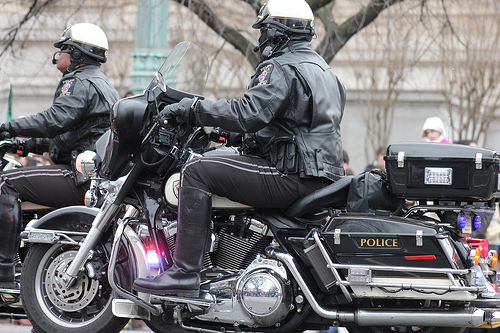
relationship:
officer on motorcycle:
[132, 0, 346, 297] [20, 42, 500, 332]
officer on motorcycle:
[0, 21, 121, 289] [0, 135, 55, 316]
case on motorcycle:
[386, 143, 500, 202] [20, 42, 500, 332]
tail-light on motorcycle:
[467, 235, 489, 259] [20, 42, 500, 332]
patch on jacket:
[249, 63, 272, 89] [192, 36, 346, 180]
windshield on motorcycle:
[157, 40, 208, 95] [20, 42, 500, 332]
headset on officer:
[251, 37, 267, 53] [132, 0, 346, 297]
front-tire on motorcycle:
[20, 243, 131, 332] [20, 42, 500, 332]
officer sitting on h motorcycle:
[132, 0, 346, 297] [20, 42, 500, 332]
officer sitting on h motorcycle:
[0, 21, 121, 289] [0, 135, 55, 316]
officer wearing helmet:
[0, 21, 121, 289] [55, 22, 108, 62]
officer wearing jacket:
[0, 21, 121, 289] [2, 63, 122, 163]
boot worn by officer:
[135, 186, 213, 298] [132, 0, 346, 297]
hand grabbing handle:
[0, 122, 11, 131] [2, 128, 11, 139]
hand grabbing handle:
[157, 100, 181, 128] [161, 115, 170, 126]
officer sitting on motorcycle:
[132, 0, 346, 297] [20, 42, 500, 332]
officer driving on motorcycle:
[132, 0, 346, 297] [20, 42, 500, 332]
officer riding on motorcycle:
[132, 0, 346, 297] [20, 42, 500, 332]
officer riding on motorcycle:
[0, 21, 121, 289] [0, 135, 55, 316]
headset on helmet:
[50, 48, 71, 64] [55, 22, 108, 62]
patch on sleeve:
[249, 63, 272, 89] [190, 74, 294, 136]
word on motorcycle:
[355, 235, 401, 251] [20, 42, 500, 332]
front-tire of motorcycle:
[20, 243, 131, 332] [20, 42, 500, 332]